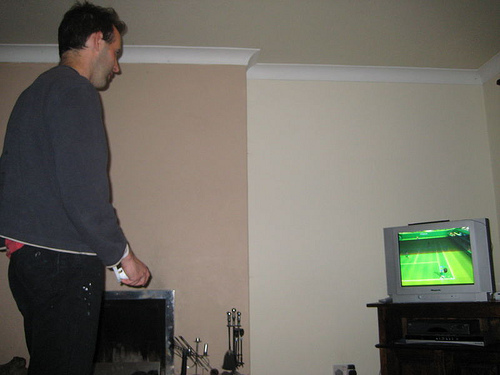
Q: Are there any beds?
A: No, there are no beds.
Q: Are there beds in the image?
A: No, there are no beds.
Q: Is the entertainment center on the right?
A: Yes, the entertainment center is on the right of the image.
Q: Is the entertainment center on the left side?
A: No, the entertainment center is on the right of the image.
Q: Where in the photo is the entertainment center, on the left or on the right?
A: The entertainment center is on the right of the image.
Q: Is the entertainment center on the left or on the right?
A: The entertainment center is on the right of the image.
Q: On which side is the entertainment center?
A: The entertainment center is on the right of the image.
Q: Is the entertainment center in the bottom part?
A: Yes, the entertainment center is in the bottom of the image.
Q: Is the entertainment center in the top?
A: No, the entertainment center is in the bottom of the image.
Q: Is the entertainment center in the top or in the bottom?
A: The entertainment center is in the bottom of the image.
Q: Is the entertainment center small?
A: Yes, the entertainment center is small.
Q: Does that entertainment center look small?
A: Yes, the entertainment center is small.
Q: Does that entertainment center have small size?
A: Yes, the entertainment center is small.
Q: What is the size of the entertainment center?
A: The entertainment center is small.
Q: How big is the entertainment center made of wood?
A: The entertainment center is small.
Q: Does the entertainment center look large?
A: No, the entertainment center is small.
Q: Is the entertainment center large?
A: No, the entertainment center is small.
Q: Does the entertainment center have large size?
A: No, the entertainment center is small.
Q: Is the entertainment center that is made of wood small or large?
A: The entertainment center is small.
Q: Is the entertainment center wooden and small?
A: Yes, the entertainment center is wooden and small.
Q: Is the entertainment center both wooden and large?
A: No, the entertainment center is wooden but small.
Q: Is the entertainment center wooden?
A: Yes, the entertainment center is wooden.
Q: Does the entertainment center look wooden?
A: Yes, the entertainment center is wooden.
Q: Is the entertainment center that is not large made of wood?
A: Yes, the entertainment center is made of wood.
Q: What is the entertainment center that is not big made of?
A: The entertainment center is made of wood.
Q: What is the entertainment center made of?
A: The entertainment center is made of wood.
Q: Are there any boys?
A: No, there are no boys.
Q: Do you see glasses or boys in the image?
A: No, there are no boys or glasses.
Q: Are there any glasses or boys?
A: No, there are no boys or glasses.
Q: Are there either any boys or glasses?
A: No, there are no boys or glasses.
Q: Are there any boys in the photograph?
A: No, there are no boys.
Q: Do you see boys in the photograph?
A: No, there are no boys.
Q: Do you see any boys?
A: No, there are no boys.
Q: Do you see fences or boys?
A: No, there are no boys or fences.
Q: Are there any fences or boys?
A: No, there are no boys or fences.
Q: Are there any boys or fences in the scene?
A: No, there are no boys or fences.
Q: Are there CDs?
A: No, there are no cds.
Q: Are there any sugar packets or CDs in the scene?
A: No, there are no CDs or sugar packets.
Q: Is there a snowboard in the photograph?
A: No, there are no snowboards.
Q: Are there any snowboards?
A: No, there are no snowboards.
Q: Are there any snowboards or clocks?
A: No, there are no snowboards or clocks.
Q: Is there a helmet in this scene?
A: No, there are no helmets.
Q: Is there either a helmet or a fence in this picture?
A: No, there are no helmets or fences.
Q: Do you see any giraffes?
A: No, there are no giraffes.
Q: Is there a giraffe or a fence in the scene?
A: No, there are no giraffes or fences.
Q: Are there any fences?
A: No, there are no fences.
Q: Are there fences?
A: No, there are no fences.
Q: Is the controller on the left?
A: Yes, the controller is on the left of the image.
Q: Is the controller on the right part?
A: No, the controller is on the left of the image.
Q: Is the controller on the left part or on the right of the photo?
A: The controller is on the left of the image.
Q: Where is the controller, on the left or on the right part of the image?
A: The controller is on the left of the image.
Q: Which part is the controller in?
A: The controller is on the left of the image.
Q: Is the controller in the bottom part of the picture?
A: Yes, the controller is in the bottom of the image.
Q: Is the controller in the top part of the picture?
A: No, the controller is in the bottom of the image.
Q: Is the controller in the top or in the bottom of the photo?
A: The controller is in the bottom of the image.